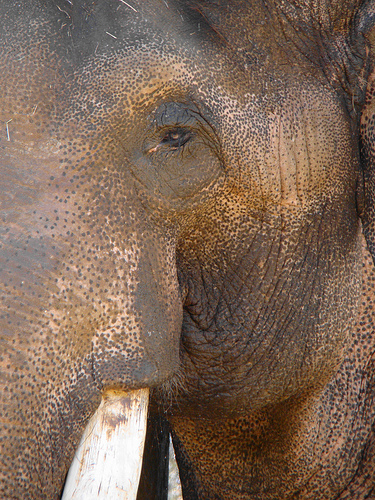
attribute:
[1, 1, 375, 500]
elephant — aged, elderly, male, brown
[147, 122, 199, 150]
eye — small, deep-set, dark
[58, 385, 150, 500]
tusk — white, ivory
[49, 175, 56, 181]
spot — black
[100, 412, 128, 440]
spot — brown